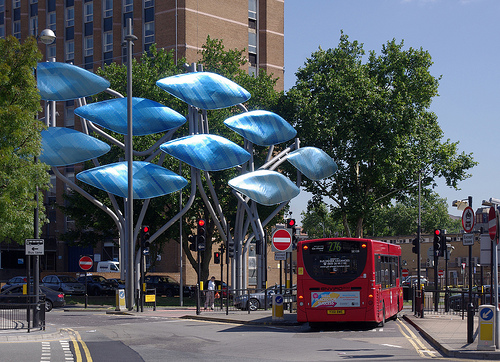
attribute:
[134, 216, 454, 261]
traffic lights — red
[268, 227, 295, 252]
sign — white, red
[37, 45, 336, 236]
structure — artistic, gray , blue 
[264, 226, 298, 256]
sign — red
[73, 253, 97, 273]
sign — red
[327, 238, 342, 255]
276 — neon, green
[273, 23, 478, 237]
tree — tall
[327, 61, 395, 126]
leaves — green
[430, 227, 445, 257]
stop light — red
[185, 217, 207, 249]
stop light — red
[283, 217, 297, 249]
stop light — red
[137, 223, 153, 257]
stop light — red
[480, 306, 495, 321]
arrow — down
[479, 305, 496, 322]
sign — blue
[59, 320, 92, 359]
lines — yellow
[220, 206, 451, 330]
bus — red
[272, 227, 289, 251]
sign — street, red, white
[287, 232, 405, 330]
bus — red, double decker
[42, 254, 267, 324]
vehicles — parked 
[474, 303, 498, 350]
white arrow — down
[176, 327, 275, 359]
street — asphalt, gray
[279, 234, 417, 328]
bus — red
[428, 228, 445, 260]
light — red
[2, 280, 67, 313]
car — driving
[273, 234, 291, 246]
stripe — white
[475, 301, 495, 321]
arrow — white